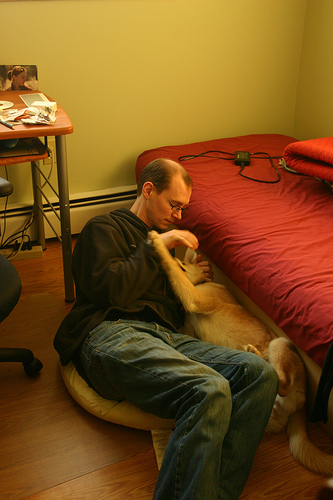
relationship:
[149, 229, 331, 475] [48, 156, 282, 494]
dog laying by man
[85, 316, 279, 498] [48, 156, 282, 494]
jeans worn by man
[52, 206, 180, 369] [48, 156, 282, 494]
shirt worn by man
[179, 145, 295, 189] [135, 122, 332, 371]
charger on bed